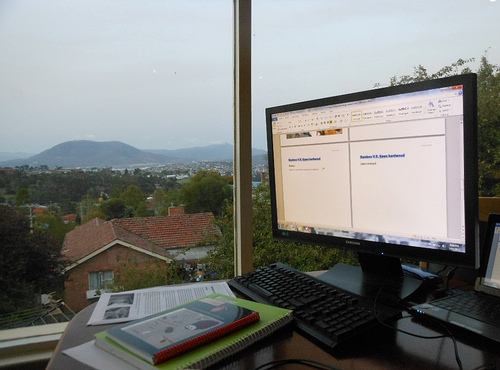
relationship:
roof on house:
[113, 221, 172, 262] [56, 208, 222, 310]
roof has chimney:
[113, 221, 172, 262] [165, 199, 182, 219]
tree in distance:
[195, 176, 226, 207] [174, 162, 237, 217]